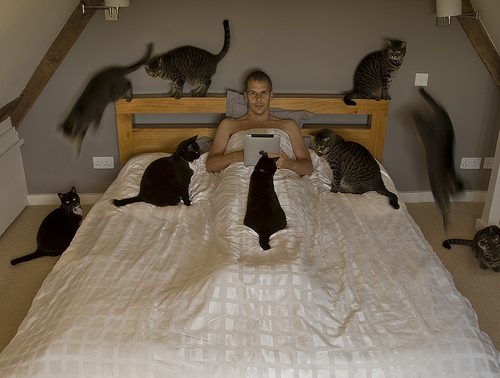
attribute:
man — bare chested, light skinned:
[205, 70, 313, 179]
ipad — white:
[244, 131, 283, 168]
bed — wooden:
[0, 91, 499, 375]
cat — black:
[109, 134, 203, 216]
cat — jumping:
[53, 32, 154, 156]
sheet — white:
[3, 152, 499, 376]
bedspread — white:
[3, 153, 498, 377]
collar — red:
[255, 164, 268, 176]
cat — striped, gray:
[307, 127, 402, 210]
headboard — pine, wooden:
[114, 95, 391, 167]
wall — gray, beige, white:
[17, 0, 499, 206]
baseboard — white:
[24, 190, 499, 206]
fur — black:
[243, 152, 288, 249]